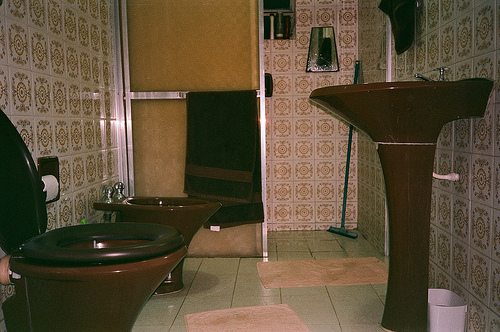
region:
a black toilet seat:
[11, 217, 188, 268]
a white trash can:
[423, 281, 468, 330]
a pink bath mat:
[179, 300, 324, 330]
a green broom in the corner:
[323, 57, 366, 241]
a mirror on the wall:
[302, 22, 342, 78]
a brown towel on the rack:
[179, 87, 272, 231]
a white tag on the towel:
[208, 222, 220, 234]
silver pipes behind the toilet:
[101, 178, 129, 223]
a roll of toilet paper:
[39, 172, 59, 202]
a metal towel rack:
[125, 85, 265, 100]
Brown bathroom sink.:
[308, 77, 430, 329]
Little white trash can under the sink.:
[425, 284, 466, 330]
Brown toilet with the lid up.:
[0, 109, 186, 329]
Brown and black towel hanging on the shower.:
[183, 89, 265, 228]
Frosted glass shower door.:
[121, 0, 263, 256]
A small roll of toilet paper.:
[40, 172, 59, 201]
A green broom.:
[326, 55, 365, 239]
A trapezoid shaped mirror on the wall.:
[303, 24, 340, 74]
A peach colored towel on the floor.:
[255, 258, 390, 287]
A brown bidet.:
[93, 187, 223, 293]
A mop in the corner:
[323, 57, 369, 237]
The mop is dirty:
[330, 60, 360, 238]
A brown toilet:
[1, 111, 180, 329]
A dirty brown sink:
[309, 73, 497, 328]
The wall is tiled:
[0, 6, 117, 233]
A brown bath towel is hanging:
[183, 85, 260, 227]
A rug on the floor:
[256, 257, 392, 287]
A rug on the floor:
[186, 303, 312, 326]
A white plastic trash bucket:
[425, 285, 465, 328]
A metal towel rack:
[132, 87, 261, 105]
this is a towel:
[188, 89, 255, 194]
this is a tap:
[113, 178, 128, 203]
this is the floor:
[201, 270, 252, 302]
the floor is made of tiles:
[192, 262, 244, 296]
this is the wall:
[26, 10, 95, 117]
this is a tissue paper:
[41, 173, 58, 195]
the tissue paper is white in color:
[46, 176, 51, 202]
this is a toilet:
[18, 222, 189, 316]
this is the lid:
[3, 132, 35, 233]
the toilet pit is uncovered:
[54, 219, 175, 254]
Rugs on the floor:
[178, 250, 392, 330]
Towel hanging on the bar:
[181, 86, 273, 233]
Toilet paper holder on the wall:
[37, 155, 60, 207]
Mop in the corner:
[328, 57, 362, 239]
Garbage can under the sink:
[424, 278, 474, 329]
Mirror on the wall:
[306, 24, 339, 74]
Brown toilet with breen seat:
[0, 115, 188, 330]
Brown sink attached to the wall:
[311, 77, 497, 330]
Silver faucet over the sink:
[410, 62, 455, 82]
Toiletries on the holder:
[265, 10, 295, 42]